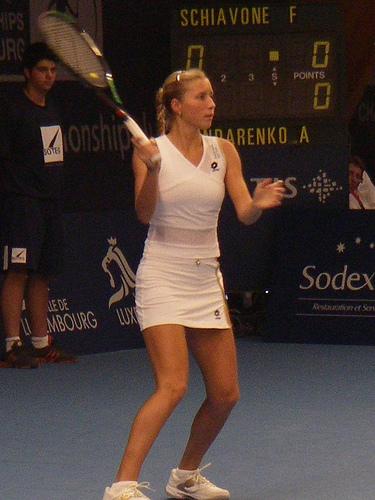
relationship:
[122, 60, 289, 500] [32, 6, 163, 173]
woman holding racket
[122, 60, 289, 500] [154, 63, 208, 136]
woman has hair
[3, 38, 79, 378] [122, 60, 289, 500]
man behind woman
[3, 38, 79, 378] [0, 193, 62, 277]
man wearing shorts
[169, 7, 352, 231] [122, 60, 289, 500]
scoreboard behind woman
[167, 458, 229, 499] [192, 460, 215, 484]
shoe has lace